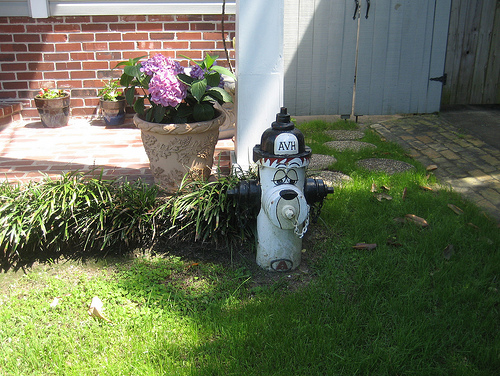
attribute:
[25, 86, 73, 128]
pot — rear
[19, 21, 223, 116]
wall — brick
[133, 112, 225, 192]
planter — large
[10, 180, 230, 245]
plants — green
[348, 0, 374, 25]
handles — black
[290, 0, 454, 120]
door — white, double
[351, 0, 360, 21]
handle — black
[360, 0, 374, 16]
handle — black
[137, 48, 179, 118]
flower — pink